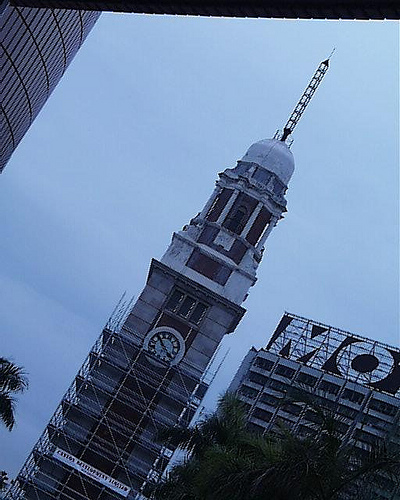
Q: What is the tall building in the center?
A: Clocktower.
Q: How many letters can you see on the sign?
A: Two.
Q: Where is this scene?
A: Tropical island.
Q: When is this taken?
A: Evening.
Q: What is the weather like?
A: Cloudy.